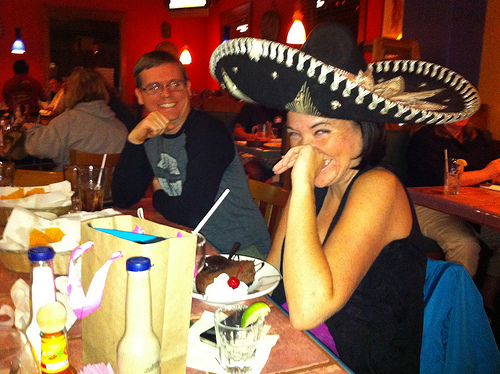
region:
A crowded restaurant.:
[15, 40, 483, 335]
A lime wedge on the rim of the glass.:
[235, 300, 270, 331]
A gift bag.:
[70, 210, 190, 365]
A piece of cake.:
[195, 245, 275, 305]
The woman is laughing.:
[250, 85, 445, 360]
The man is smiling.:
[125, 40, 250, 235]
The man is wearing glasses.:
[130, 55, 185, 125]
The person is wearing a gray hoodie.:
[15, 55, 120, 175]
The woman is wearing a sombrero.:
[200, 10, 485, 140]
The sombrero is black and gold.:
[205, 25, 485, 140]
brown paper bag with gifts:
[83, 193, 191, 362]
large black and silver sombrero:
[240, 28, 489, 116]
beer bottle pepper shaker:
[128, 257, 144, 372]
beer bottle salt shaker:
[17, 239, 60, 334]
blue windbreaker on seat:
[430, 259, 494, 358]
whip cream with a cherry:
[208, 265, 250, 306]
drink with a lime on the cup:
[209, 303, 280, 371]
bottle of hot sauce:
[25, 299, 93, 372]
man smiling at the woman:
[105, 43, 265, 206]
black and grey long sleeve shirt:
[115, 133, 265, 214]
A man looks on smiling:
[125, 49, 195, 140]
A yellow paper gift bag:
[78, 202, 192, 363]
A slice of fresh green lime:
[243, 297, 266, 323]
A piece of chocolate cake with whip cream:
[196, 249, 261, 302]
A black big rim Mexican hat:
[217, 41, 478, 118]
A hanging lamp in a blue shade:
[8, 10, 35, 57]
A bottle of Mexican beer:
[121, 257, 158, 367]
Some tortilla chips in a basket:
[10, 215, 75, 247]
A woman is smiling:
[273, 110, 363, 180]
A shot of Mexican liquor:
[211, 317, 261, 366]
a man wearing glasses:
[123, 41, 195, 131]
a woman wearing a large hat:
[216, 27, 436, 204]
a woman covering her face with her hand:
[258, 121, 403, 201]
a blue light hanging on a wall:
[8, 26, 30, 75]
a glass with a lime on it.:
[210, 294, 267, 372]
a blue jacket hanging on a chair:
[398, 253, 483, 370]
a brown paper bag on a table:
[65, 212, 222, 369]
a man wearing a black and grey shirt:
[122, 49, 204, 228]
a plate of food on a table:
[170, 241, 274, 319]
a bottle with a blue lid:
[106, 250, 163, 372]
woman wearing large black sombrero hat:
[205, 14, 497, 369]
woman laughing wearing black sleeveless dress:
[204, 9, 476, 371]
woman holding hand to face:
[203, 17, 474, 363]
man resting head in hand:
[105, 42, 254, 285]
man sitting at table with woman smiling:
[110, 42, 270, 273]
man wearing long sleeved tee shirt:
[109, 46, 264, 274]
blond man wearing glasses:
[107, 42, 259, 277]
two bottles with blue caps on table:
[26, 240, 168, 370]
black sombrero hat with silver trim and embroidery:
[204, 16, 486, 129]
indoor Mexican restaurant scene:
[6, 0, 498, 364]